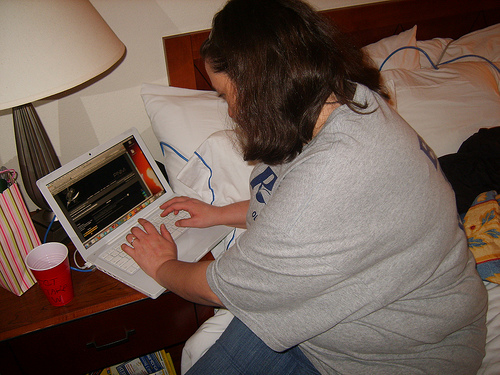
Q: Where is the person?
A: Bedroom.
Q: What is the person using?
A: Computer.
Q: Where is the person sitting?
A: Bed.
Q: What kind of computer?
A: Laptop.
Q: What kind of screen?
A: Computer.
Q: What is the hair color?
A: Brown.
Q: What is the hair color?
A: Brown.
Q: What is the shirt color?
A: Grey.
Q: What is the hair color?
A: Brown.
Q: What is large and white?
A: Lamp shade.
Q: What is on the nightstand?
A: A laptop.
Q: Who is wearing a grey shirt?
A: A woman.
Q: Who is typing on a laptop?
A: A woman.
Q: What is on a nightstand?
A: A lamp.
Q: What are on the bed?
A: Pillows.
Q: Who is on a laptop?
A: A woman.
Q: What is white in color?
A: A laptop.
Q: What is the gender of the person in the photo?
A: Female.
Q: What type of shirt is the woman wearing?
A: A grey t-shirt.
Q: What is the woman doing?
A: Sitting on the bed, working on her computer.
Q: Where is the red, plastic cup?
A: On the nightstand to the left of the computer.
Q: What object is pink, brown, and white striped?
A: A gift bag.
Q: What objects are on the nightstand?
A: A lamp, gift bag, red cup, and a laptop.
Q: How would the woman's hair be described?
A: Dark brown and shoulder length.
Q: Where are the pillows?
A: On the bed against the headboard.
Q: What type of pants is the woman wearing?
A: Jeans.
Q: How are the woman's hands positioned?
A: On the keyboard ready to type.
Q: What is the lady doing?
A: Using the computer.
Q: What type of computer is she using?
A: A mackbook.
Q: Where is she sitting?
A: On a bed.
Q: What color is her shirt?
A: Grey.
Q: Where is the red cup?
A: On her nightstand.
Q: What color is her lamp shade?
A: White.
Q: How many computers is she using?
A: One.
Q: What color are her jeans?
A: Blue.